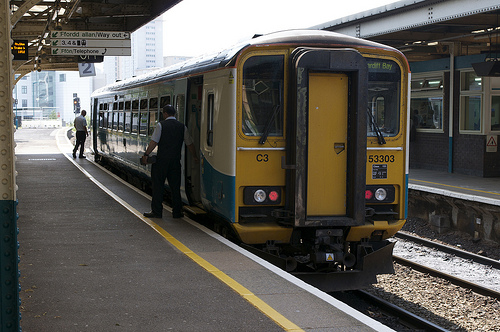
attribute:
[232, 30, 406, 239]
train — yellow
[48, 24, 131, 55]
sign — white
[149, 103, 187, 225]
man — bald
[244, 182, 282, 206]
mold — black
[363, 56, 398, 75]
destination — green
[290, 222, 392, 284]
bumper — large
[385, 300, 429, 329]
tracks — gray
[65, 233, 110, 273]
platform — gray, grey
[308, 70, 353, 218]
door — yellow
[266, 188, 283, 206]
light — off, red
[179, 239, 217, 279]
line — yellow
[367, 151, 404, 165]
number — 53303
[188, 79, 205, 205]
door — open